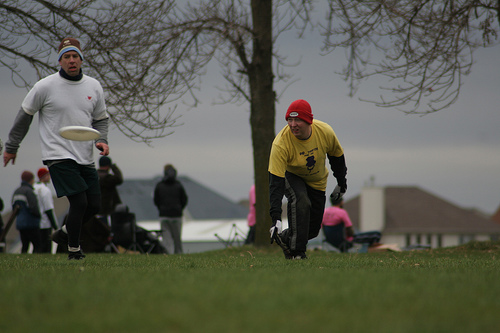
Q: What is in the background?
A: The sky.